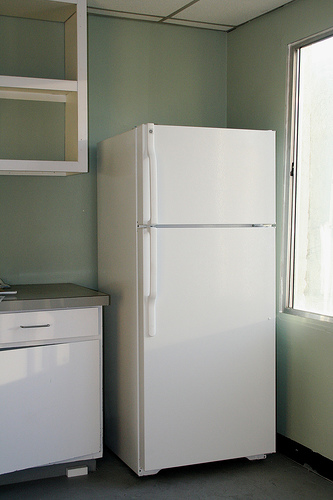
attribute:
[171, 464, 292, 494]
floor — gray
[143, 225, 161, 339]
handle — white, refrigerator handle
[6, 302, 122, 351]
drawer — white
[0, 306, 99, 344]
drawer — white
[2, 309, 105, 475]
cabinet — white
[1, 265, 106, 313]
counter — gray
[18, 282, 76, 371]
cabinet — white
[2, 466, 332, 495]
flooring — grey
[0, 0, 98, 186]
cabinets — white, open cabinets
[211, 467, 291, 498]
tiles — white, ceiling tiles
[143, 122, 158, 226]
handle — white, refrigerator handle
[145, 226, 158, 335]
handle — white, refrigerator handle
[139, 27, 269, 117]
walls — green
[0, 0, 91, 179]
cabinets — white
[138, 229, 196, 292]
door — white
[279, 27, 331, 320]
window — long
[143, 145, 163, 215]
handle — white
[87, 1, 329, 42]
tile — white, ceiling tiles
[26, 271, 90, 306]
counter top — gray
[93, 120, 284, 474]
refrigerator — white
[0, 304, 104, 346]
drawer — white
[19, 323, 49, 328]
handle — silver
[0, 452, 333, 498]
floor covering — worn, gray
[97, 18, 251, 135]
wall — green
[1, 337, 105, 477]
cabinet — bottom cabinet, slightly open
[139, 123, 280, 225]
door — white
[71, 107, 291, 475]
refrigerator — large, white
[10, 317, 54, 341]
handle — silver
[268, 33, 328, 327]
frame — silver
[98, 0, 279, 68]
frame — dark frame